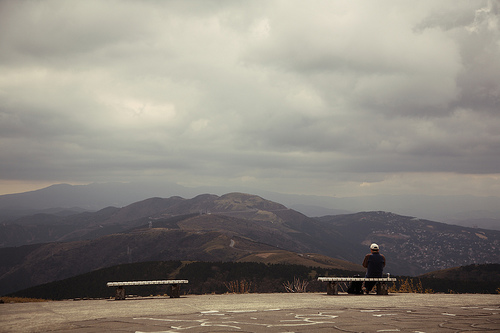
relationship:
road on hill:
[229, 233, 239, 249] [4, 212, 499, 294]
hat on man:
[370, 242, 379, 251] [363, 244, 387, 295]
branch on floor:
[284, 276, 309, 293] [2, 294, 499, 332]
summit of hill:
[169, 195, 185, 201] [1, 190, 312, 244]